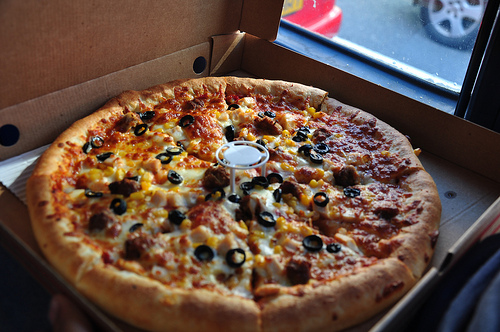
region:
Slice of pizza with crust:
[245, 181, 347, 330]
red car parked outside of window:
[286, 3, 348, 35]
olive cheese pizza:
[29, 81, 443, 319]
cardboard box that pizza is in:
[35, 33, 264, 71]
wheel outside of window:
[418, 0, 483, 45]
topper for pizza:
[214, 131, 269, 191]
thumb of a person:
[35, 286, 100, 327]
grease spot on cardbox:
[440, 175, 455, 212]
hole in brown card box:
[177, 47, 217, 74]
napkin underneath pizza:
[0, 151, 31, 201]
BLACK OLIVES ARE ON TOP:
[167, 173, 186, 185]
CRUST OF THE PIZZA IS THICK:
[288, 291, 353, 324]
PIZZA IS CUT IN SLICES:
[241, 195, 376, 317]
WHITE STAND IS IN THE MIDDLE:
[217, 142, 267, 174]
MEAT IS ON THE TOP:
[285, 245, 307, 283]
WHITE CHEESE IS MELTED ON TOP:
[187, 168, 205, 180]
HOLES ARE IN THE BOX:
[3, 124, 17, 146]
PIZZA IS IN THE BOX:
[51, 43, 428, 330]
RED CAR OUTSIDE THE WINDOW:
[312, 8, 335, 26]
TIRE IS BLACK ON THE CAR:
[430, 33, 440, 40]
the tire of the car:
[416, 4, 478, 47]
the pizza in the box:
[41, 82, 498, 327]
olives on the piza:
[213, 238, 260, 271]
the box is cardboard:
[6, 37, 497, 329]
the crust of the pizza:
[270, 294, 344, 330]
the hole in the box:
[3, 122, 35, 147]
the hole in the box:
[184, 48, 228, 76]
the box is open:
[26, 77, 490, 329]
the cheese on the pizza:
[157, 126, 203, 193]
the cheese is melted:
[171, 157, 231, 196]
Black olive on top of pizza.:
[295, 215, 327, 272]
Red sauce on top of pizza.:
[168, 95, 215, 136]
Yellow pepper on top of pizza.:
[122, 134, 174, 212]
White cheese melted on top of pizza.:
[153, 173, 236, 230]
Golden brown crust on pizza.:
[155, 74, 295, 114]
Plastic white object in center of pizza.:
[208, 106, 270, 206]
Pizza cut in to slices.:
[316, 95, 442, 261]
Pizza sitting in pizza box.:
[383, 122, 468, 262]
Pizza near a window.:
[357, 28, 443, 177]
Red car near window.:
[308, 8, 351, 37]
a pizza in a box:
[16, 45, 454, 321]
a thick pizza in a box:
[4, 32, 452, 323]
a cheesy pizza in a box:
[12, 39, 487, 327]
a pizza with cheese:
[22, 31, 482, 326]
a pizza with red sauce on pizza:
[32, 24, 497, 331]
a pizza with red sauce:
[43, 27, 490, 328]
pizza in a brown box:
[44, 32, 486, 317]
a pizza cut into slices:
[32, 18, 482, 330]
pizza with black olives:
[14, 21, 482, 323]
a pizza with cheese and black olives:
[46, 25, 486, 315]